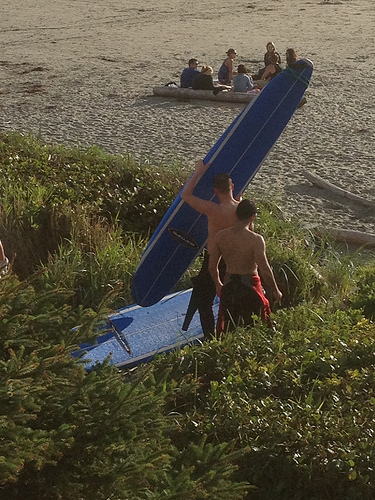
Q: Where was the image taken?
A: It was taken at the beach.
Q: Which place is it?
A: It is a beach.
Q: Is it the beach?
A: Yes, it is the beach.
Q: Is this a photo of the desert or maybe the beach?
A: It is showing the beach.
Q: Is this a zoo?
A: No, it is a beach.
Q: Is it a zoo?
A: No, it is a beach.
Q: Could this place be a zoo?
A: No, it is a beach.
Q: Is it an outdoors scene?
A: Yes, it is outdoors.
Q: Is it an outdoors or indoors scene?
A: It is outdoors.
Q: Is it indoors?
A: No, it is outdoors.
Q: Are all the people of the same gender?
A: No, they are both male and female.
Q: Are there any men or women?
A: Yes, there is a woman.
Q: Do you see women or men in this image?
A: Yes, there is a woman.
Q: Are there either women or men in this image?
A: Yes, there is a woman.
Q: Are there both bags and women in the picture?
A: No, there is a woman but no bags.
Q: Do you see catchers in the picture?
A: No, there are no catchers.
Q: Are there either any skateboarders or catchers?
A: No, there are no catchers or skateboarders.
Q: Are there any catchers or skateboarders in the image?
A: No, there are no catchers or skateboarders.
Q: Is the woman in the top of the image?
A: Yes, the woman is in the top of the image.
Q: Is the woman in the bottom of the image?
A: No, the woman is in the top of the image.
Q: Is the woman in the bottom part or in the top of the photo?
A: The woman is in the top of the image.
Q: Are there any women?
A: Yes, there is a woman.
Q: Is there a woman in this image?
A: Yes, there is a woman.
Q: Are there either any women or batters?
A: Yes, there is a woman.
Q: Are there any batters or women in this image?
A: Yes, there is a woman.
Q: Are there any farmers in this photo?
A: No, there are no farmers.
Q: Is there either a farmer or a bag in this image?
A: No, there are no farmers or bags.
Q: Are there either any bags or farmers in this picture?
A: No, there are no farmers or bags.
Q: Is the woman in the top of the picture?
A: Yes, the woman is in the top of the image.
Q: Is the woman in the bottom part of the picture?
A: No, the woman is in the top of the image.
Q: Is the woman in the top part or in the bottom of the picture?
A: The woman is in the top of the image.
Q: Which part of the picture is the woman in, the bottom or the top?
A: The woman is in the top of the image.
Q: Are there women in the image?
A: Yes, there is a woman.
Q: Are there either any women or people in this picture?
A: Yes, there is a woman.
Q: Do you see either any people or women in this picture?
A: Yes, there is a woman.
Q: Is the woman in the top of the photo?
A: Yes, the woman is in the top of the image.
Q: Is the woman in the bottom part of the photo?
A: No, the woman is in the top of the image.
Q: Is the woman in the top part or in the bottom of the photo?
A: The woman is in the top of the image.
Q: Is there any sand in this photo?
A: Yes, there is sand.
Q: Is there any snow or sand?
A: Yes, there is sand.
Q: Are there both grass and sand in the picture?
A: Yes, there are both sand and grass.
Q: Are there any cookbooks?
A: No, there are no cookbooks.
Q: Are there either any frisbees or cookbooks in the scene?
A: No, there are no cookbooks or frisbees.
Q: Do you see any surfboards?
A: Yes, there is a surfboard.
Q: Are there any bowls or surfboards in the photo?
A: Yes, there is a surfboard.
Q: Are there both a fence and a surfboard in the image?
A: No, there is a surfboard but no fences.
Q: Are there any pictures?
A: No, there are no pictures.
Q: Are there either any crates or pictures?
A: No, there are no pictures or crates.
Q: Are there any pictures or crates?
A: No, there are no pictures or crates.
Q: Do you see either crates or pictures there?
A: No, there are no pictures or crates.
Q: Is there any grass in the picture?
A: Yes, there is grass.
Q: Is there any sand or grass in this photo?
A: Yes, there is grass.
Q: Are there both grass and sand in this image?
A: Yes, there are both grass and sand.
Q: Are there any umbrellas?
A: No, there are no umbrellas.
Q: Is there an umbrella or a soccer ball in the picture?
A: No, there are no umbrellas or soccer balls.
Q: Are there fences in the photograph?
A: No, there are no fences.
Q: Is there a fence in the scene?
A: No, there are no fences.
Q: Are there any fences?
A: No, there are no fences.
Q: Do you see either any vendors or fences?
A: No, there are no fences or vendors.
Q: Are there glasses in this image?
A: No, there are no glasses.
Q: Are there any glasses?
A: No, there are no glasses.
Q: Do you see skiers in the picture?
A: No, there are no skiers.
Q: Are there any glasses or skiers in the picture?
A: No, there are no skiers or glasses.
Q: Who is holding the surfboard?
A: The man is holding the surfboard.